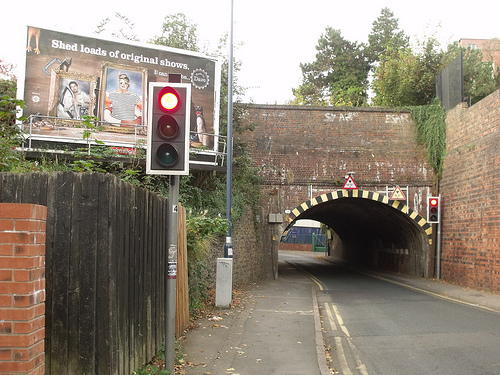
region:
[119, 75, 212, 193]
a red traffic signal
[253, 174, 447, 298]
an arched tunnel over the street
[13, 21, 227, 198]
a large billboard on the side of the street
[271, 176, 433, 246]
yellow and black lines on the arch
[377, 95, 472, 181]
ivy is covering the brick wall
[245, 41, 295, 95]
an overcast sky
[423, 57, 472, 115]
a black fence on teh brick wall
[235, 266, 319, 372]
a sidewalk runs parallel to the street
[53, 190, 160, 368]
a grey wooden fence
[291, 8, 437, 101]
a group of trees in the background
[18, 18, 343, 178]
Bill board in the background.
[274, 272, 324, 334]
Lines on the road.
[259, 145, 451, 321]
Tunnel under the bricks.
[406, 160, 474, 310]
Red light on the pole.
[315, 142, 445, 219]
Yield sign over the tunnel.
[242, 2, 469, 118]
Trees in the background.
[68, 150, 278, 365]
Wood fence on the side of the road.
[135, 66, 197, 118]
Red light on the light pole.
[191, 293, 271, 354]
Leaves on the tree.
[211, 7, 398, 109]
Sky in the background.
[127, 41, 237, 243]
Light on the pole.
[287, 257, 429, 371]
Lines on the road.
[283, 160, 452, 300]
Tunnel over the road.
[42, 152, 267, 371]
Wood on the fence.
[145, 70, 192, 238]
Red light on the pole.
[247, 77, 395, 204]
Bricks over a tunnel.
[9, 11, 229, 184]
A billboard behind a traffic signal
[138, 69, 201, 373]
A traffic signal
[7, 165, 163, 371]
A wooden fence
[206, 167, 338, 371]
A sidewalk leading into a tunnel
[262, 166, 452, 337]
A roadway tunnel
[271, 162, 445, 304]
Warning signs over a tunnel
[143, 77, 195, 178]
A row of traffic lights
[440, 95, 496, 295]
A brick wall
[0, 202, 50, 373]
Red brickwork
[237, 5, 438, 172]
Trees over a bridge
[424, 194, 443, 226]
traffic light by underpass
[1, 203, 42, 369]
red brick column by fence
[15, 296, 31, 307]
individual brick of column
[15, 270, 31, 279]
individual brick of column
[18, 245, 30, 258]
individual brick of column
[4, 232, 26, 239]
individual brick of column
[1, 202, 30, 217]
individual brick of column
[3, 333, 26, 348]
individual brick of column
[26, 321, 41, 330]
individual brick of column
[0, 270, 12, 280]
individual brick of column